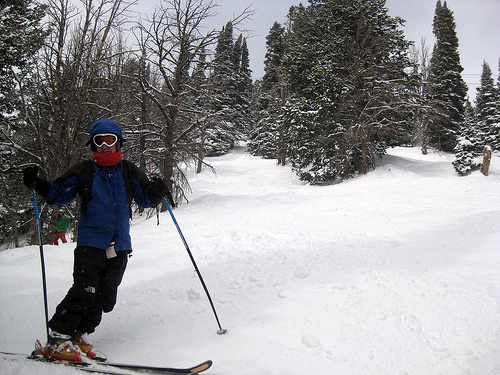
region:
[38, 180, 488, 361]
There is snow on the ground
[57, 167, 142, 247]
His coat is blue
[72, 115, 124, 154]
he is wearing goggles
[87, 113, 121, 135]
his hat is blue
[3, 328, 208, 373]
skiis on his feet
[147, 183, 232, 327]
Holding two ski poles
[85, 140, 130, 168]
his scarf is red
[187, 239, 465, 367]
The snow on the ground is white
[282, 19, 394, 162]
the trees have snow on them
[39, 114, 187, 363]
He is wearing snow gear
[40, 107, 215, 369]
man is skiing down a small hill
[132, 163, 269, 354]
man is holding ski poles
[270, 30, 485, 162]
trees have snow on them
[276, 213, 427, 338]
lots of snow on the ground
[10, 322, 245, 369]
man wearing skis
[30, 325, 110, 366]
the man is wearing ski boots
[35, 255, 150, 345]
the man is wearing black pants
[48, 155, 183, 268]
the man is wearing a blue jacket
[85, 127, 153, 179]
the man is wearing snow goggles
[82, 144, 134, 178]
the man has an orange scarf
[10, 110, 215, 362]
A man on skis.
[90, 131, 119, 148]
Goggles on a man's face.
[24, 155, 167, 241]
A blue and black ski jacket.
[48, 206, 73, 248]
A woman walking on snow.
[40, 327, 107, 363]
Brown ski boots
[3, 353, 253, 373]
A pair of skis on snow.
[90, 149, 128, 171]
A red scarf on man's neck.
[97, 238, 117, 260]
A white ski tag ticket.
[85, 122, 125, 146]
A blue hood on a man's head.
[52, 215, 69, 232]
A green ski jacket.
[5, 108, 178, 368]
a skier on skis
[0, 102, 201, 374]
a skier standing on snow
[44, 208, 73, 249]
green jacket and red pants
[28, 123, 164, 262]
a blue and black jacket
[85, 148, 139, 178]
red scarf around neck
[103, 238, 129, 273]
white tag hanging from jacket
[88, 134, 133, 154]
white goggles on face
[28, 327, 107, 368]
red and gold boots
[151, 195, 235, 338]
blue and black ski poles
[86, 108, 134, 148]
blue hat on head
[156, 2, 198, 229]
This is a tree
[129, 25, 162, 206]
This is a tree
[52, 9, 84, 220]
This is a tree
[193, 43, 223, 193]
This is a tree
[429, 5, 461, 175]
This is a tree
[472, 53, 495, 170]
This is a tree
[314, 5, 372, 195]
This is a tree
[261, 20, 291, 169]
This is a tree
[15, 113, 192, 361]
This is a person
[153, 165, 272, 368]
This is a ski pole